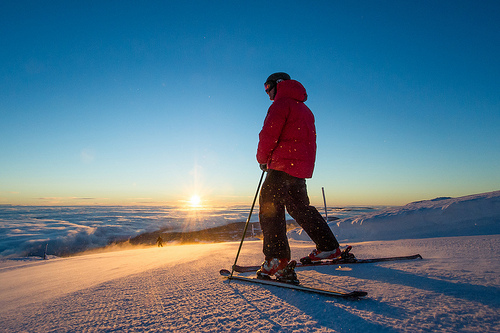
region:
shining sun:
[130, 170, 228, 240]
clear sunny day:
[28, 44, 465, 325]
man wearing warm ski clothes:
[214, 62, 429, 308]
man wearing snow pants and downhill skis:
[212, 65, 437, 312]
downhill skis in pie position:
[207, 237, 457, 310]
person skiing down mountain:
[125, 225, 185, 259]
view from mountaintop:
[23, 176, 205, 283]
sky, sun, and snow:
[27, 162, 222, 311]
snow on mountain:
[391, 177, 491, 248]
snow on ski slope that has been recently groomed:
[69, 262, 221, 329]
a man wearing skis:
[216, 61, 426, 304]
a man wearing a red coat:
[252, 70, 318, 181]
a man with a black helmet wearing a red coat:
[253, 67, 318, 182]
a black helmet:
[261, 70, 293, 85]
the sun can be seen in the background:
[178, 186, 211, 223]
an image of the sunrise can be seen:
[85, 160, 242, 216]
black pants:
[255, 180, 335, 247]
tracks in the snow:
[47, 283, 229, 328]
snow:
[42, 262, 219, 332]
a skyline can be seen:
[5, 176, 244, 216]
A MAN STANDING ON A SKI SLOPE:
[205, 68, 434, 316]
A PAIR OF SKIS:
[210, 247, 453, 308]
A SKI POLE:
[216, 157, 281, 284]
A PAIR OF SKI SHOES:
[242, 231, 358, 281]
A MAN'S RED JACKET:
[241, 74, 341, 185]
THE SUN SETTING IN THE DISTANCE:
[114, 176, 234, 272]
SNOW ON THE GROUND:
[91, 266, 207, 313]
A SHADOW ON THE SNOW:
[196, 264, 496, 326]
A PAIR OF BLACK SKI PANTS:
[260, 171, 352, 266]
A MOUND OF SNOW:
[342, 188, 498, 250]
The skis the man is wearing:
[213, 252, 430, 306]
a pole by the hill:
[312, 183, 333, 218]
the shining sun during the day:
[175, 181, 208, 221]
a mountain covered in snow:
[10, 187, 498, 332]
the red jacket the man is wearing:
[253, 74, 315, 180]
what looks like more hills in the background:
[10, 199, 244, 244]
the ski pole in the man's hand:
[213, 165, 273, 283]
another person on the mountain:
[155, 235, 165, 247]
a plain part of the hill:
[130, 222, 258, 243]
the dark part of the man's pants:
[254, 154, 337, 272]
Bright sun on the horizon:
[178, 175, 223, 231]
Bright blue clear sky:
[7, 65, 498, 184]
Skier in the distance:
[144, 225, 175, 257]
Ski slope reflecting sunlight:
[33, 225, 465, 327]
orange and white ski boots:
[251, 241, 351, 295]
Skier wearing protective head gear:
[250, 67, 314, 103]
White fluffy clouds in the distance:
[2, 192, 256, 243]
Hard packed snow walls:
[318, 177, 498, 251]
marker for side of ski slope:
[318, 179, 341, 230]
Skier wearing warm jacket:
[247, 70, 331, 181]